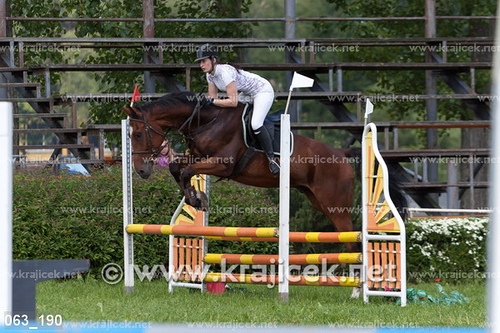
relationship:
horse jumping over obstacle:
[124, 90, 409, 257] [118, 110, 408, 310]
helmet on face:
[193, 44, 216, 63] [185, 38, 230, 80]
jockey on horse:
[192, 41, 286, 138] [113, 94, 376, 241]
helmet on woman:
[194, 44, 216, 59] [195, 42, 279, 172]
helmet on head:
[193, 44, 216, 63] [194, 42, 223, 75]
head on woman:
[194, 42, 223, 75] [191, 43, 281, 177]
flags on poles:
[281, 69, 378, 116] [258, 105, 447, 267]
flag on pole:
[128, 85, 140, 103] [123, 100, 136, 120]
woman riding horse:
[186, 49, 301, 190] [93, 108, 416, 253]